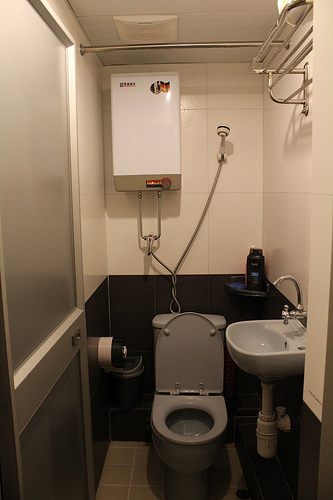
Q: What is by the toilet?
A: A sink.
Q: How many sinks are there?
A: One.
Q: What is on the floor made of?
A: Tile.